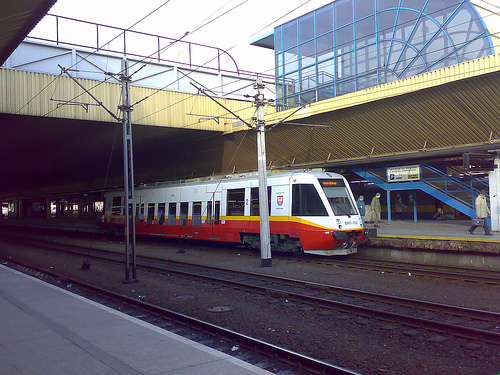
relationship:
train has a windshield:
[5, 161, 365, 264] [321, 176, 352, 221]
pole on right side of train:
[257, 134, 270, 258] [150, 170, 353, 250]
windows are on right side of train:
[150, 193, 210, 228] [144, 173, 359, 254]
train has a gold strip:
[5, 161, 365, 264] [221, 212, 261, 224]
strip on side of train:
[221, 212, 261, 224] [5, 161, 365, 264]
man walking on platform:
[370, 190, 384, 218] [407, 217, 470, 251]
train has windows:
[5, 161, 365, 264] [148, 196, 214, 224]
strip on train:
[221, 215, 302, 225] [104, 169, 383, 264]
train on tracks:
[5, 161, 365, 264] [89, 228, 479, 362]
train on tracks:
[5, 161, 365, 264] [351, 250, 484, 299]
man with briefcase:
[469, 190, 484, 230] [463, 209, 484, 229]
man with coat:
[469, 190, 484, 230] [476, 194, 484, 220]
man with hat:
[468, 190, 492, 236] [469, 187, 484, 198]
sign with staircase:
[381, 167, 424, 185] [357, 164, 478, 227]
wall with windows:
[267, 19, 484, 138] [278, 1, 478, 97]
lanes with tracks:
[31, 223, 484, 373] [344, 255, 484, 288]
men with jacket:
[356, 194, 367, 225] [353, 197, 369, 218]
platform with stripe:
[5, 264, 212, 373] [7, 263, 232, 369]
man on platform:
[468, 190, 492, 236] [382, 217, 466, 242]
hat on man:
[472, 190, 484, 197] [460, 183, 484, 238]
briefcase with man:
[467, 211, 484, 227] [471, 187, 484, 244]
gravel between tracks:
[208, 294, 369, 341] [163, 250, 443, 372]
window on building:
[271, 30, 296, 73] [265, 2, 481, 105]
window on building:
[294, 15, 314, 64] [271, 3, 484, 126]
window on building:
[328, 10, 354, 50] [265, 2, 481, 105]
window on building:
[311, 15, 339, 38] [271, 3, 484, 126]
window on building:
[356, 2, 378, 21] [275, 0, 476, 85]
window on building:
[369, 8, 399, 47] [265, 2, 481, 105]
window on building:
[314, 36, 335, 66] [277, 20, 491, 158]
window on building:
[281, 51, 299, 81] [251, 4, 498, 174]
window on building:
[280, 69, 300, 96] [253, 0, 496, 156]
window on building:
[337, 56, 358, 85] [251, 4, 498, 174]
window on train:
[318, 182, 358, 220] [95, 167, 365, 257]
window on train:
[290, 181, 330, 220] [95, 167, 365, 257]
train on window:
[97, 161, 366, 263] [251, 185, 272, 215]